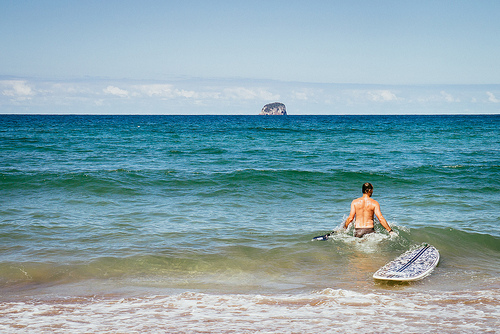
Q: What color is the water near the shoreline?
A: Light green.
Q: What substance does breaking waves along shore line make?
A: Foam.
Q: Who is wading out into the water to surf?
A: The man.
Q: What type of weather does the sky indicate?
A: Clear and sunny.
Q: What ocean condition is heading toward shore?
A: A wave.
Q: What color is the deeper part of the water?
A: Green.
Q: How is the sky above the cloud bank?
A: Clear.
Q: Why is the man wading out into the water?
A: To surf.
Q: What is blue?
A: Ocean.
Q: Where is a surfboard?
A: In the water.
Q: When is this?
A: Day time.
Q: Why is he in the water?
A: To surf.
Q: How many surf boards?
A: 1.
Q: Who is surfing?
A: The man.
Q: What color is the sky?
A: Blue.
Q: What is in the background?
A: A rock.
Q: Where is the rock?
A: Water.